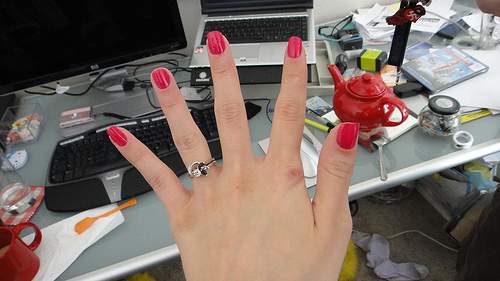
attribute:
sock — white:
[350, 224, 431, 279]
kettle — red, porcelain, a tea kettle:
[321, 54, 416, 144]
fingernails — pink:
[69, 46, 364, 208]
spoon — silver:
[366, 128, 406, 195]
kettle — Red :
[336, 71, 403, 123]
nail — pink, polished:
[336, 121, 360, 149]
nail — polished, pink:
[285, 37, 305, 57]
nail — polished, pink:
[207, 31, 226, 53]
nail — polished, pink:
[152, 69, 172, 90]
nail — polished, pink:
[105, 126, 128, 146]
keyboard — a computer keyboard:
[45, 101, 232, 211]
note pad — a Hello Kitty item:
[0, 146, 32, 172]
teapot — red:
[315, 55, 408, 135]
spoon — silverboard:
[371, 130, 401, 188]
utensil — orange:
[70, 196, 140, 235]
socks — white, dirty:
[353, 230, 430, 280]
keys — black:
[202, 15, 309, 41]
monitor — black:
[3, 5, 185, 103]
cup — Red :
[0, 221, 41, 279]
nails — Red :
[334, 118, 362, 151]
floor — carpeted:
[343, 184, 470, 279]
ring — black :
[171, 155, 213, 190]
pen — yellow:
[305, 117, 328, 132]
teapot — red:
[296, 57, 438, 187]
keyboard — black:
[42, 106, 222, 213]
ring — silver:
[187, 156, 216, 176]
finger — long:
[201, 29, 251, 164]